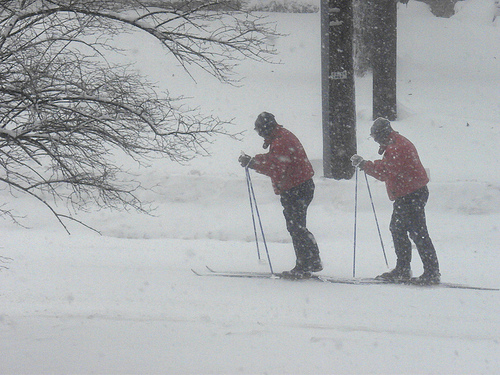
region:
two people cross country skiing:
[188, 101, 498, 301]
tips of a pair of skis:
[187, 260, 219, 282]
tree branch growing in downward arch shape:
[39, 92, 164, 140]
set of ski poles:
[350, 156, 390, 279]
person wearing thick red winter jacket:
[236, 108, 323, 275]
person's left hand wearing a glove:
[346, 148, 370, 175]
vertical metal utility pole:
[319, 0, 359, 182]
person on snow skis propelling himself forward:
[188, 108, 334, 283]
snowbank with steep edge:
[140, 167, 225, 245]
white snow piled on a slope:
[403, 2, 498, 69]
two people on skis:
[193, 103, 499, 300]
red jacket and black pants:
[348, 139, 448, 280]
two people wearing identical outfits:
[212, 96, 477, 289]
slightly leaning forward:
[228, 96, 337, 278]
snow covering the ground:
[5, 10, 495, 374]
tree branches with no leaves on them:
[2, 1, 276, 241]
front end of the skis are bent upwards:
[190, 261, 218, 280]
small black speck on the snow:
[464, 121, 471, 131]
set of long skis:
[325, 268, 495, 293]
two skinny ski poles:
[343, 156, 400, 273]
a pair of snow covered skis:
[190, 262, 334, 279]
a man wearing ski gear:
[226, 108, 328, 279]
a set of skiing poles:
[242, 165, 274, 272]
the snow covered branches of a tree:
[2, 0, 286, 225]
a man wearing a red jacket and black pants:
[344, 118, 446, 285]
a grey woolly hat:
[366, 115, 393, 136]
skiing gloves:
[350, 151, 363, 167]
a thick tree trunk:
[318, 5, 358, 181]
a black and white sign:
[328, 69, 346, 81]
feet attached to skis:
[375, 261, 442, 285]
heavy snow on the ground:
[44, 278, 192, 350]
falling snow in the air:
[119, 161, 217, 231]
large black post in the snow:
[314, 30, 369, 174]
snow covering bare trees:
[55, 80, 154, 120]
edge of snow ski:
[176, 257, 225, 281]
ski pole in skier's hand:
[228, 147, 272, 248]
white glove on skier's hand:
[341, 148, 376, 170]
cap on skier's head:
[242, 99, 307, 151]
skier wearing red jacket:
[365, 132, 436, 197]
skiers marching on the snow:
[237, 106, 450, 292]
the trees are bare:
[3, 8, 267, 243]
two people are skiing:
[174, 54, 464, 314]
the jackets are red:
[239, 122, 454, 212]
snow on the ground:
[141, 281, 383, 372]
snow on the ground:
[94, 243, 279, 335]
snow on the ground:
[436, 180, 498, 282]